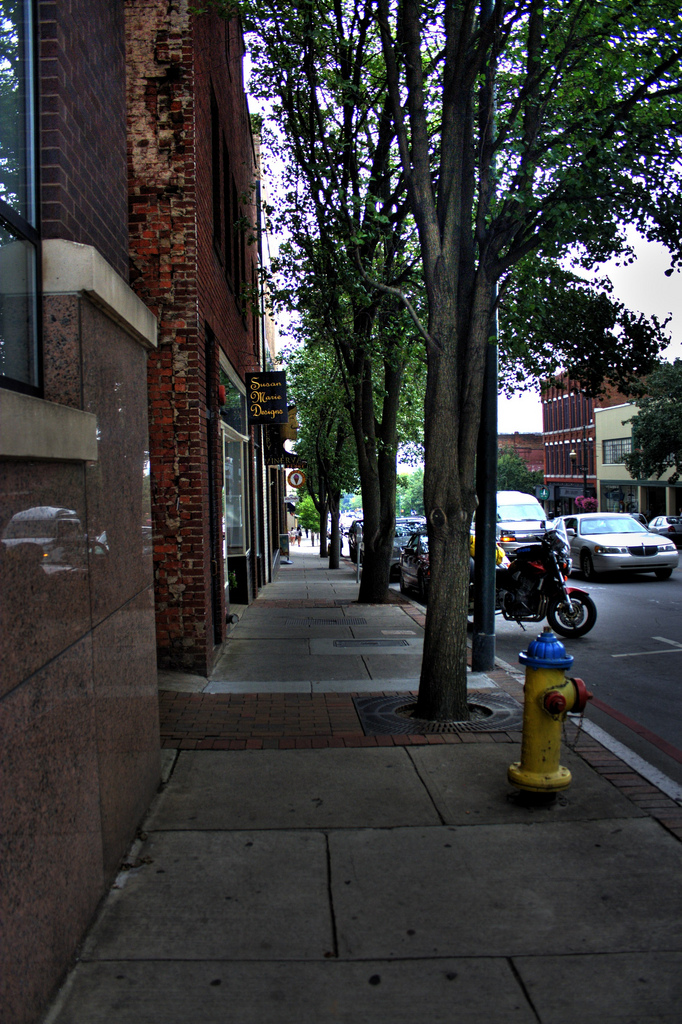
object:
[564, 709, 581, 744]
chain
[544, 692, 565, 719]
lug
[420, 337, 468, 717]
tree trunk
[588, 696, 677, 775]
line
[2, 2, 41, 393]
window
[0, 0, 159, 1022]
building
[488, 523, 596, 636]
motorcycle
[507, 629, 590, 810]
fire hydrant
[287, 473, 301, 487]
sign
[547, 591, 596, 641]
wheel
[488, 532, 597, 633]
bike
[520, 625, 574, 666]
top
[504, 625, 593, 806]
hydrant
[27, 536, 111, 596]
car reflection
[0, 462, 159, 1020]
wall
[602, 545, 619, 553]
headlight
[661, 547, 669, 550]
headlight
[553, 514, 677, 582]
car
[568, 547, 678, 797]
street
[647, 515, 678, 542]
car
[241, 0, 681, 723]
tree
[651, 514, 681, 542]
vehicles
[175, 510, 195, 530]
brick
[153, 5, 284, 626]
building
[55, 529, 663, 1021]
sidewalk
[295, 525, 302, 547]
person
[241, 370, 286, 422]
sign